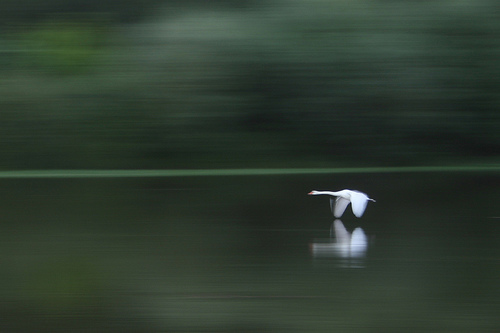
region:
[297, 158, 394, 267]
bird in flight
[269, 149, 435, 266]
bird above water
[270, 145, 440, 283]
white bird flying above water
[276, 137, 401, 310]
bird's reflection on water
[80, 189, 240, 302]
green background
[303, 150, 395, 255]
bird flying below green line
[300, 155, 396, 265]
white bird with orange beak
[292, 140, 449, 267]
white bird with long neck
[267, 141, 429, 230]
white bird in mid-flight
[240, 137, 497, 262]
white bird in motion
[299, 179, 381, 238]
white bird flying above the water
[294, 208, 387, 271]
flying white bird's reflection on water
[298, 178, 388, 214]
white bird flying above water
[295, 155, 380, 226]
white goose above water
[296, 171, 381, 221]
a fast flying white bird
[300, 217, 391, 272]
reflection of white bird on water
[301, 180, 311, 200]
orange beak of bird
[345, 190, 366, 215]
bird wing covered in white feathers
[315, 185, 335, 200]
white feathers on bird neck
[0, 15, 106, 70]
blurry green leaves on tree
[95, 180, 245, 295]
calm surface of water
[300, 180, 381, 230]
large white bird flying over body of water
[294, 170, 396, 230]
A Goose flying fast across the water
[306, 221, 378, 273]
The reflection of the goose in the water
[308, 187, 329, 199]
The head of the goose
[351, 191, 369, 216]
The wing of the goose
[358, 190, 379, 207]
The Tail of the goose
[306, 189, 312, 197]
The Beak of the Goose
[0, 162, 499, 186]
A Blurry stripe of the shore line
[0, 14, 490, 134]
Blurry image of the background vegitation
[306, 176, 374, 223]
A goose in flight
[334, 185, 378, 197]
The backside of the goose